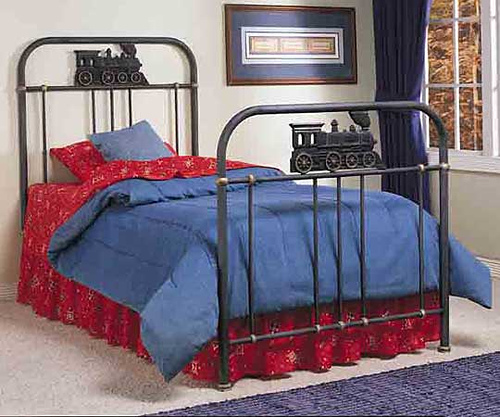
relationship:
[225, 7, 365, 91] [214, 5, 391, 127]
hanging on wall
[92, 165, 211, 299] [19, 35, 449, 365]
comforter on bed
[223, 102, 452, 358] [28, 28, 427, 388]
board of bed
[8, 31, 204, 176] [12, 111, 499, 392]
headboard on bed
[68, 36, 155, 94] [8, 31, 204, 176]
engine on headboard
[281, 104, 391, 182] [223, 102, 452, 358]
engine on board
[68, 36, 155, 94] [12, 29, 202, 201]
engine on headboard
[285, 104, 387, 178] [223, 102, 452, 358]
engine on board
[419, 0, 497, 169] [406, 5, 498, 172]
panes on window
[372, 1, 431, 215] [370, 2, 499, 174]
blue curtains on window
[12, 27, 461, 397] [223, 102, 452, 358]
bed has board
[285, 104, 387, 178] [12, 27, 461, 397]
engine on bed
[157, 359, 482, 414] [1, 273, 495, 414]
blue rug on floor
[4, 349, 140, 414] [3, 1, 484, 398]
floor in bedroom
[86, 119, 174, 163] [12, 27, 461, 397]
blue pillow on bed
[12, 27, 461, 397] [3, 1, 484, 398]
bed in bedroom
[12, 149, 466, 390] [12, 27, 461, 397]
mattress on bed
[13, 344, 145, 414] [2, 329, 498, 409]
carpet on floor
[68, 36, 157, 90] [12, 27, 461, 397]
train on bed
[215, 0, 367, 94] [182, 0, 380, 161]
picture on wall